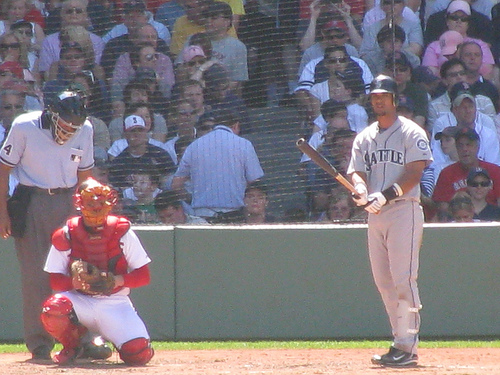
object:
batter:
[344, 73, 435, 368]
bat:
[294, 137, 366, 201]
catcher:
[36, 175, 152, 365]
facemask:
[72, 178, 117, 229]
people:
[109, 21, 177, 112]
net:
[0, 0, 500, 223]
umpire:
[2, 92, 113, 359]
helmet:
[365, 73, 400, 107]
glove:
[363, 182, 401, 216]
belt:
[27, 186, 74, 200]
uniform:
[36, 216, 155, 364]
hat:
[451, 126, 479, 143]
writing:
[362, 149, 404, 174]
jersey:
[344, 117, 433, 204]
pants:
[362, 200, 426, 355]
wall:
[0, 222, 500, 343]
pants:
[40, 289, 150, 352]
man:
[168, 109, 265, 223]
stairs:
[236, 99, 304, 218]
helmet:
[52, 88, 89, 128]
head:
[367, 75, 396, 117]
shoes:
[377, 349, 418, 367]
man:
[431, 126, 499, 223]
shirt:
[431, 160, 498, 206]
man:
[106, 116, 176, 195]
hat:
[120, 115, 147, 135]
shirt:
[0, 111, 94, 192]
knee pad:
[117, 334, 154, 367]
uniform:
[345, 117, 433, 354]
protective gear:
[49, 216, 134, 295]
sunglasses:
[468, 181, 490, 188]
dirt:
[2, 347, 500, 374]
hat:
[443, 0, 471, 14]